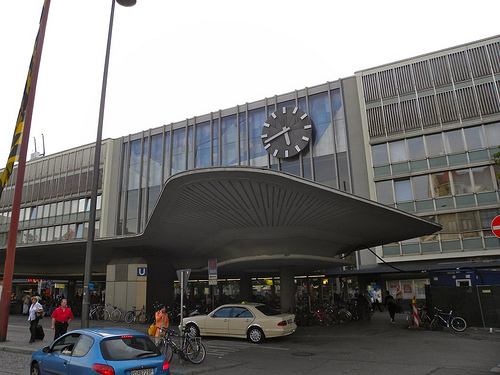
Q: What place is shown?
A: It is a shopping center.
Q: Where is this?
A: This is at the shopping center.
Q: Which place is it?
A: It is a shopping center.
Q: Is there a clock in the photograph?
A: Yes, there is a clock.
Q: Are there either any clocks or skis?
A: Yes, there is a clock.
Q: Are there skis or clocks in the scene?
A: Yes, there is a clock.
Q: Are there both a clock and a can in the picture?
A: No, there is a clock but no cans.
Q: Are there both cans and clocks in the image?
A: No, there is a clock but no cans.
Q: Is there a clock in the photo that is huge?
A: Yes, there is a huge clock.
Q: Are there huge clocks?
A: Yes, there is a huge clock.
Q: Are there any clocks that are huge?
A: Yes, there is a huge clock.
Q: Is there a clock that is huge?
A: Yes, there is a clock that is huge.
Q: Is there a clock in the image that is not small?
A: Yes, there is a huge clock.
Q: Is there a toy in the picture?
A: No, there are no toys.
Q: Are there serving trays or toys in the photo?
A: No, there are no toys or serving trays.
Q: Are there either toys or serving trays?
A: No, there are no toys or serving trays.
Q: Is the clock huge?
A: Yes, the clock is huge.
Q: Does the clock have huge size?
A: Yes, the clock is huge.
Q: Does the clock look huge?
A: Yes, the clock is huge.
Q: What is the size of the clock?
A: The clock is huge.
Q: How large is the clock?
A: The clock is huge.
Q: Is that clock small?
A: No, the clock is huge.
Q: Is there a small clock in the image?
A: No, there is a clock but it is huge.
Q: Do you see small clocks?
A: No, there is a clock but it is huge.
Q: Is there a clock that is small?
A: No, there is a clock but it is huge.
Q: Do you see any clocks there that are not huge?
A: No, there is a clock but it is huge.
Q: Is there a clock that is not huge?
A: No, there is a clock but it is huge.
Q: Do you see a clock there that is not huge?
A: No, there is a clock but it is huge.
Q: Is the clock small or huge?
A: The clock is huge.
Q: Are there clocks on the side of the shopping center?
A: Yes, there is a clock on the side of the shopping center.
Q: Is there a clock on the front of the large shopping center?
A: Yes, there is a clock on the front of the shopping center.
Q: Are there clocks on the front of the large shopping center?
A: Yes, there is a clock on the front of the shopping center.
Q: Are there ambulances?
A: No, there are no ambulances.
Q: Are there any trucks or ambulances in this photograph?
A: No, there are no ambulances or trucks.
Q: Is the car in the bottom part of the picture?
A: Yes, the car is in the bottom of the image.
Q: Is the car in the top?
A: No, the car is in the bottom of the image.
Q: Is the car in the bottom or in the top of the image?
A: The car is in the bottom of the image.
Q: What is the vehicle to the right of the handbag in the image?
A: The vehicle is a car.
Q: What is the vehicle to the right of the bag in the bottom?
A: The vehicle is a car.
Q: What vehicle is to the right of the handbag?
A: The vehicle is a car.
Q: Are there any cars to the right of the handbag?
A: Yes, there is a car to the right of the handbag.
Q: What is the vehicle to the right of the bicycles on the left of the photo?
A: The vehicle is a car.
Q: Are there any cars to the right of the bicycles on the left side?
A: Yes, there is a car to the right of the bicycles.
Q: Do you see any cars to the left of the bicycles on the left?
A: No, the car is to the right of the bikes.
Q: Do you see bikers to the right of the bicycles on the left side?
A: No, there is a car to the right of the bicycles.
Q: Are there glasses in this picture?
A: No, there are no glasses.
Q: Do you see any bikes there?
A: Yes, there are bikes.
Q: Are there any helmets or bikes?
A: Yes, there are bikes.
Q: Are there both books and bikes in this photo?
A: No, there are bikes but no books.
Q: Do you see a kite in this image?
A: No, there are no kites.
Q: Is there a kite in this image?
A: No, there are no kites.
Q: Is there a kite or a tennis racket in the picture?
A: No, there are no kites or rackets.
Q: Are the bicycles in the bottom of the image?
A: Yes, the bicycles are in the bottom of the image.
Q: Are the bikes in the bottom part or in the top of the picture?
A: The bikes are in the bottom of the image.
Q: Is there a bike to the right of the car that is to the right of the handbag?
A: Yes, there are bikes to the right of the car.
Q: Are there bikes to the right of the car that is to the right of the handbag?
A: Yes, there are bikes to the right of the car.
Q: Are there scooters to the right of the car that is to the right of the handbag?
A: No, there are bikes to the right of the car.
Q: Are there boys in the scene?
A: No, there are no boys.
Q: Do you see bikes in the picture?
A: Yes, there are bikes.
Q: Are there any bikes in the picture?
A: Yes, there are bikes.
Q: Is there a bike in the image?
A: Yes, there are bikes.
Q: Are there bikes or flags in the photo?
A: Yes, there are bikes.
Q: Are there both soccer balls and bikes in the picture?
A: No, there are bikes but no soccer balls.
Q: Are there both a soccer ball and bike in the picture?
A: No, there are bikes but no soccer balls.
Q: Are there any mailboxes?
A: No, there are no mailboxes.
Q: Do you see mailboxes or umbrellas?
A: No, there are no mailboxes or umbrellas.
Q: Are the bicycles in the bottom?
A: Yes, the bicycles are in the bottom of the image.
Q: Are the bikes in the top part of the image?
A: No, the bikes are in the bottom of the image.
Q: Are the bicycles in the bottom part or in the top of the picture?
A: The bicycles are in the bottom of the image.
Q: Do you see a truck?
A: No, there are no trucks.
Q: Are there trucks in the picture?
A: No, there are no trucks.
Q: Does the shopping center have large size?
A: Yes, the shopping center is large.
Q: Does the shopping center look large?
A: Yes, the shopping center is large.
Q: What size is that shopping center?
A: The shopping center is large.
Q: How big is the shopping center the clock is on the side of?
A: The shopping center is large.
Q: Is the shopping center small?
A: No, the shopping center is large.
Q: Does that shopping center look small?
A: No, the shopping center is large.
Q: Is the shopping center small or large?
A: The shopping center is large.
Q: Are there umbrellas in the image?
A: No, there are no umbrellas.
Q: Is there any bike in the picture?
A: Yes, there are bikes.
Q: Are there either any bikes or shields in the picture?
A: Yes, there are bikes.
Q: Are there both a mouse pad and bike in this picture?
A: No, there are bikes but no mouse pads.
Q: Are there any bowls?
A: No, there are no bowls.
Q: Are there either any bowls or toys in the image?
A: No, there are no bowls or toys.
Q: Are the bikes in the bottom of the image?
A: Yes, the bikes are in the bottom of the image.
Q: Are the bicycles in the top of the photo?
A: No, the bicycles are in the bottom of the image.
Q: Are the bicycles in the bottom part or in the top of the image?
A: The bicycles are in the bottom of the image.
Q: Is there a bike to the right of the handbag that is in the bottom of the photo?
A: Yes, there are bikes to the right of the handbag.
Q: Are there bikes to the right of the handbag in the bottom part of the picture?
A: Yes, there are bikes to the right of the handbag.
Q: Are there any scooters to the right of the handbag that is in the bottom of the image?
A: No, there are bikes to the right of the handbag.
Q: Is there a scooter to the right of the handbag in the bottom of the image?
A: No, there are bikes to the right of the handbag.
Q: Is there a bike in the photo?
A: Yes, there is a bike.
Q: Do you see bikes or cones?
A: Yes, there is a bike.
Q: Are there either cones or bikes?
A: Yes, there is a bike.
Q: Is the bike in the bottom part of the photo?
A: Yes, the bike is in the bottom of the image.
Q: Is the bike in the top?
A: No, the bike is in the bottom of the image.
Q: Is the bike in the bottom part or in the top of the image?
A: The bike is in the bottom of the image.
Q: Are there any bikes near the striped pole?
A: Yes, there is a bike near the pole.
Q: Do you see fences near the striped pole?
A: No, there is a bike near the pole.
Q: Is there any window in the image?
A: Yes, there are windows.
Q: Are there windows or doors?
A: Yes, there are windows.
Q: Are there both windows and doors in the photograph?
A: Yes, there are both windows and doors.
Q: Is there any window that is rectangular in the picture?
A: Yes, there are rectangular windows.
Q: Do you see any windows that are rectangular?
A: Yes, there are rectangular windows.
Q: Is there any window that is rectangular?
A: Yes, there are windows that are rectangular.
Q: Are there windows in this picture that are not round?
A: Yes, there are rectangular windows.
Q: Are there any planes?
A: No, there are no planes.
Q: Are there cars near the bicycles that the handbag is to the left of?
A: Yes, there is a car near the bicycles.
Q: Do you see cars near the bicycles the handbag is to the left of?
A: Yes, there is a car near the bicycles.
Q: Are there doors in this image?
A: Yes, there are doors.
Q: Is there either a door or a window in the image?
A: Yes, there are doors.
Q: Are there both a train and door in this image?
A: No, there are doors but no trains.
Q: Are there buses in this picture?
A: No, there are no buses.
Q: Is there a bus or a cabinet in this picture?
A: No, there are no buses or cabinets.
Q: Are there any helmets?
A: No, there are no helmets.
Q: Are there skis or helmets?
A: No, there are no helmets or skis.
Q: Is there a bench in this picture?
A: No, there are no benches.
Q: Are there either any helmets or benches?
A: No, there are no benches or helmets.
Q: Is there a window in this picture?
A: Yes, there are windows.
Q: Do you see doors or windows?
A: Yes, there are windows.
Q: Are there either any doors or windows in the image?
A: Yes, there are windows.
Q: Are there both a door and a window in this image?
A: Yes, there are both a window and a door.